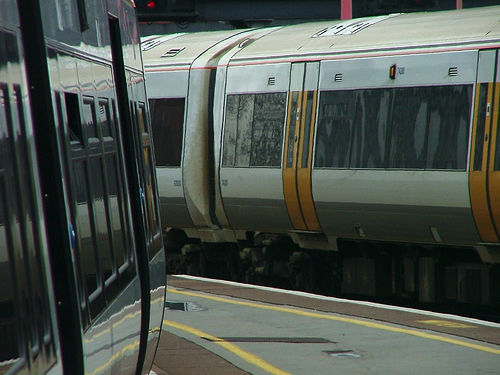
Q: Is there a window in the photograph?
A: Yes, there are windows.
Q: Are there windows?
A: Yes, there are windows.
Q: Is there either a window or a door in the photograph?
A: Yes, there are windows.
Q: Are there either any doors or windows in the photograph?
A: Yes, there are windows.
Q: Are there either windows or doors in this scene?
A: Yes, there are windows.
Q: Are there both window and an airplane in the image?
A: No, there are windows but no airplanes.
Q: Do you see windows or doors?
A: Yes, there is a window.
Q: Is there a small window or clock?
A: Yes, there is a small window.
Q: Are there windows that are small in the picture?
A: Yes, there is a small window.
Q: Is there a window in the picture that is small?
A: Yes, there is a window that is small.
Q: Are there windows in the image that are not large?
A: Yes, there is a small window.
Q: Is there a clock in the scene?
A: No, there are no clocks.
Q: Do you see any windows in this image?
A: Yes, there is a window.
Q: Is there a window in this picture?
A: Yes, there is a window.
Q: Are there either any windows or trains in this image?
A: Yes, there is a window.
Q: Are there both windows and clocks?
A: No, there is a window but no clocks.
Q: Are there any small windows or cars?
A: Yes, there is a small window.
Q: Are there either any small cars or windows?
A: Yes, there is a small window.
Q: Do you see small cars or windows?
A: Yes, there is a small window.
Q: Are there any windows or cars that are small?
A: Yes, the window is small.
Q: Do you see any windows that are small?
A: Yes, there is a small window.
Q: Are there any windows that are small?
A: Yes, there is a window that is small.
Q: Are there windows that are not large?
A: Yes, there is a small window.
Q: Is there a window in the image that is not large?
A: Yes, there is a small window.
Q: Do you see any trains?
A: Yes, there is a train.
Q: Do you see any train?
A: Yes, there is a train.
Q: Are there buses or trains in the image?
A: Yes, there is a train.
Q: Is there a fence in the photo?
A: No, there are no fences.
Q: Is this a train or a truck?
A: This is a train.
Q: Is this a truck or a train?
A: This is a train.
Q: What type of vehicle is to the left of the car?
A: The vehicle is a train.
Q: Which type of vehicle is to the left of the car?
A: The vehicle is a train.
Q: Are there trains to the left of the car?
A: Yes, there is a train to the left of the car.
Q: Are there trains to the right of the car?
A: No, the train is to the left of the car.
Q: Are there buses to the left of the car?
A: No, there is a train to the left of the car.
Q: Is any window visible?
A: Yes, there is a window.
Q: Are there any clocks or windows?
A: Yes, there is a window.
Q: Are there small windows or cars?
A: Yes, there is a small window.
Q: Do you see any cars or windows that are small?
A: Yes, the window is small.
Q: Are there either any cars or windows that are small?
A: Yes, the window is small.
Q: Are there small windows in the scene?
A: Yes, there is a small window.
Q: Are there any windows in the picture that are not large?
A: Yes, there is a small window.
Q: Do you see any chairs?
A: No, there are no chairs.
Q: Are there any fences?
A: No, there are no fences.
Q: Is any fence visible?
A: No, there are no fences.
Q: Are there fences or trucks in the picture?
A: No, there are no fences or trucks.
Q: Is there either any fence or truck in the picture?
A: No, there are no fences or trucks.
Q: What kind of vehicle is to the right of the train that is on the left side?
A: The vehicle is a car.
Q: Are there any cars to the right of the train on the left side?
A: Yes, there is a car to the right of the train.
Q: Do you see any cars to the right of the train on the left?
A: Yes, there is a car to the right of the train.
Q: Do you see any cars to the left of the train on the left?
A: No, the car is to the right of the train.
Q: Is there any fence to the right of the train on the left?
A: No, there is a car to the right of the train.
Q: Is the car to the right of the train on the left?
A: Yes, the car is to the right of the train.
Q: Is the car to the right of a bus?
A: No, the car is to the right of the train.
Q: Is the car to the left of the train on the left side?
A: No, the car is to the right of the train.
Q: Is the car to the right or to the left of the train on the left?
A: The car is to the right of the train.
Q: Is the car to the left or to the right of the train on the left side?
A: The car is to the right of the train.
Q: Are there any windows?
A: Yes, there is a window.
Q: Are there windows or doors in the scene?
A: Yes, there is a window.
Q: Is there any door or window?
A: Yes, there is a window.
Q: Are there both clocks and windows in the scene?
A: No, there is a window but no clocks.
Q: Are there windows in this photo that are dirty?
A: Yes, there is a dirty window.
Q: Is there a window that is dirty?
A: Yes, there is a window that is dirty.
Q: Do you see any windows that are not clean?
A: Yes, there is a dirty window.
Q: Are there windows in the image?
A: Yes, there is a window.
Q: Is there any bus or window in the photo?
A: Yes, there is a window.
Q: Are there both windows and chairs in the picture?
A: No, there is a window but no chairs.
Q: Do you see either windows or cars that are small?
A: Yes, the window is small.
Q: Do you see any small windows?
A: Yes, there is a small window.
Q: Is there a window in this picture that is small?
A: Yes, there is a window that is small.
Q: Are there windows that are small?
A: Yes, there is a window that is small.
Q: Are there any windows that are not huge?
A: Yes, there is a small window.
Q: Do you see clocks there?
A: No, there are no clocks.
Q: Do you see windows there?
A: Yes, there is a window.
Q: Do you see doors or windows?
A: Yes, there is a window.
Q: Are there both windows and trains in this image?
A: Yes, there are both a window and a train.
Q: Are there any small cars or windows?
A: Yes, there is a small window.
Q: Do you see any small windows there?
A: Yes, there is a small window.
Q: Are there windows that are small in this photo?
A: Yes, there is a small window.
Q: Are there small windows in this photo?
A: Yes, there is a small window.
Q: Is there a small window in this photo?
A: Yes, there is a small window.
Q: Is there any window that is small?
A: Yes, there is a window that is small.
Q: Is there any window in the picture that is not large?
A: Yes, there is a small window.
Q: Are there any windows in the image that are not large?
A: Yes, there is a small window.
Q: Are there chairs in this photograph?
A: No, there are no chairs.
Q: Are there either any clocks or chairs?
A: No, there are no chairs or clocks.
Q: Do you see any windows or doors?
A: Yes, there is a window.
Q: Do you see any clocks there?
A: No, there are no clocks.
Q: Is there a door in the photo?
A: Yes, there is a door.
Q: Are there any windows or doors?
A: Yes, there is a door.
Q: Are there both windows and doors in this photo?
A: Yes, there are both a door and a window.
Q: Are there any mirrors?
A: No, there are no mirrors.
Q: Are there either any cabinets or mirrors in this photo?
A: No, there are no mirrors or cabinets.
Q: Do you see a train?
A: Yes, there is a train.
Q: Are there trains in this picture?
A: Yes, there is a train.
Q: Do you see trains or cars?
A: Yes, there is a train.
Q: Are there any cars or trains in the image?
A: Yes, there is a train.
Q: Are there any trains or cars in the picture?
A: Yes, there is a train.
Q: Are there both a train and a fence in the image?
A: No, there is a train but no fences.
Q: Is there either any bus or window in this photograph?
A: Yes, there is a window.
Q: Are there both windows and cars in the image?
A: Yes, there are both a window and a car.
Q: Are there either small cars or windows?
A: Yes, there is a small window.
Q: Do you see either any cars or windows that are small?
A: Yes, the window is small.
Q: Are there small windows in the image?
A: Yes, there is a small window.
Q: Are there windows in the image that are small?
A: Yes, there is a window that is small.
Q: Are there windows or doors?
A: Yes, there is a window.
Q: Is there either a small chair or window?
A: Yes, there is a small window.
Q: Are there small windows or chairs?
A: Yes, there is a small window.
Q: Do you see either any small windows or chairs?
A: Yes, there is a small window.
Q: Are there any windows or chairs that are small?
A: Yes, the window is small.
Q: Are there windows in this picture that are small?
A: Yes, there is a small window.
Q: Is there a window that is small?
A: Yes, there is a window that is small.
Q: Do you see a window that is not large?
A: Yes, there is a small window.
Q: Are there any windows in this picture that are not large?
A: Yes, there is a small window.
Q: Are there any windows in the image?
A: Yes, there is a window.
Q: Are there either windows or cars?
A: Yes, there is a window.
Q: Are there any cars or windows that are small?
A: Yes, the window is small.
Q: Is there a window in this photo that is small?
A: Yes, there is a window that is small.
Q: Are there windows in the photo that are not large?
A: Yes, there is a small window.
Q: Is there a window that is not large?
A: Yes, there is a small window.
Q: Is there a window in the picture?
A: Yes, there is a window.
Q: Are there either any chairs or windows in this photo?
A: Yes, there is a window.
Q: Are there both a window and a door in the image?
A: Yes, there are both a window and a door.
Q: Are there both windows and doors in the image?
A: Yes, there are both a window and a door.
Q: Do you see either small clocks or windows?
A: Yes, there is a small window.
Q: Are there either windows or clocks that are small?
A: Yes, the window is small.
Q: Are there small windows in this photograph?
A: Yes, there is a small window.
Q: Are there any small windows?
A: Yes, there is a small window.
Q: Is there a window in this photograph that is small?
A: Yes, there is a window that is small.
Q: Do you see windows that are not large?
A: Yes, there is a small window.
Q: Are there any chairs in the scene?
A: No, there are no chairs.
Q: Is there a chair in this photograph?
A: No, there are no chairs.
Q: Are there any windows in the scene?
A: Yes, there is a window.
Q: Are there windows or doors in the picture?
A: Yes, there is a window.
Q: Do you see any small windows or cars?
A: Yes, there is a small window.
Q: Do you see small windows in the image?
A: Yes, there is a small window.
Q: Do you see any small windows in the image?
A: Yes, there is a small window.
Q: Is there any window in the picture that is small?
A: Yes, there is a window that is small.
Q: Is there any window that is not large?
A: Yes, there is a small window.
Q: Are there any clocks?
A: No, there are no clocks.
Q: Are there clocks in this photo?
A: No, there are no clocks.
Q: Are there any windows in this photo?
A: Yes, there is a window.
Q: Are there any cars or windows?
A: Yes, there is a window.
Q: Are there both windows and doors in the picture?
A: Yes, there are both a window and doors.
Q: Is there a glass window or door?
A: Yes, there is a glass window.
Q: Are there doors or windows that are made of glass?
A: Yes, the window is made of glass.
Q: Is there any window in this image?
A: Yes, there is a window.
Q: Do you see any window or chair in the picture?
A: Yes, there is a window.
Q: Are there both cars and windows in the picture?
A: Yes, there are both a window and a car.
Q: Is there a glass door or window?
A: Yes, there is a glass window.